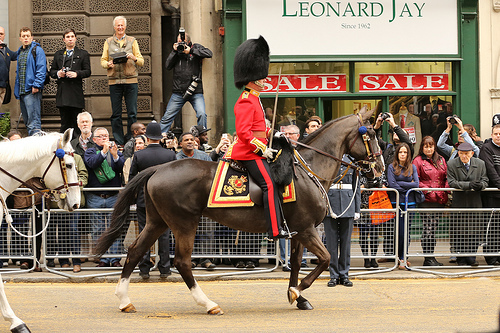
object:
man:
[233, 66, 299, 238]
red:
[239, 106, 251, 115]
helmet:
[235, 35, 270, 91]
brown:
[158, 185, 168, 200]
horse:
[93, 107, 386, 315]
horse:
[0, 128, 81, 332]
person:
[160, 28, 214, 136]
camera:
[174, 28, 187, 54]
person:
[389, 143, 419, 266]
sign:
[357, 73, 448, 93]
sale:
[362, 75, 445, 89]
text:
[261, 76, 342, 90]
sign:
[248, 1, 456, 59]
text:
[280, 0, 427, 23]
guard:
[233, 35, 299, 238]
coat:
[413, 155, 449, 206]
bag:
[366, 191, 394, 225]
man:
[84, 127, 128, 268]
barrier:
[405, 186, 500, 276]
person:
[436, 115, 480, 162]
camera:
[448, 116, 460, 125]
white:
[11, 144, 34, 154]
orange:
[382, 201, 389, 210]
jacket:
[13, 42, 47, 99]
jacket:
[166, 43, 212, 97]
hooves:
[121, 305, 139, 314]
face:
[60, 151, 84, 212]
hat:
[455, 143, 477, 150]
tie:
[66, 51, 74, 59]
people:
[99, 15, 146, 147]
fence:
[0, 187, 500, 278]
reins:
[294, 134, 349, 177]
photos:
[113, 51, 128, 65]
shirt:
[101, 37, 150, 86]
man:
[51, 29, 93, 134]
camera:
[60, 66, 73, 76]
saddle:
[207, 160, 297, 208]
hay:
[0, 277, 500, 332]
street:
[3, 281, 499, 333]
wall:
[0, 2, 480, 145]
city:
[0, 0, 500, 173]